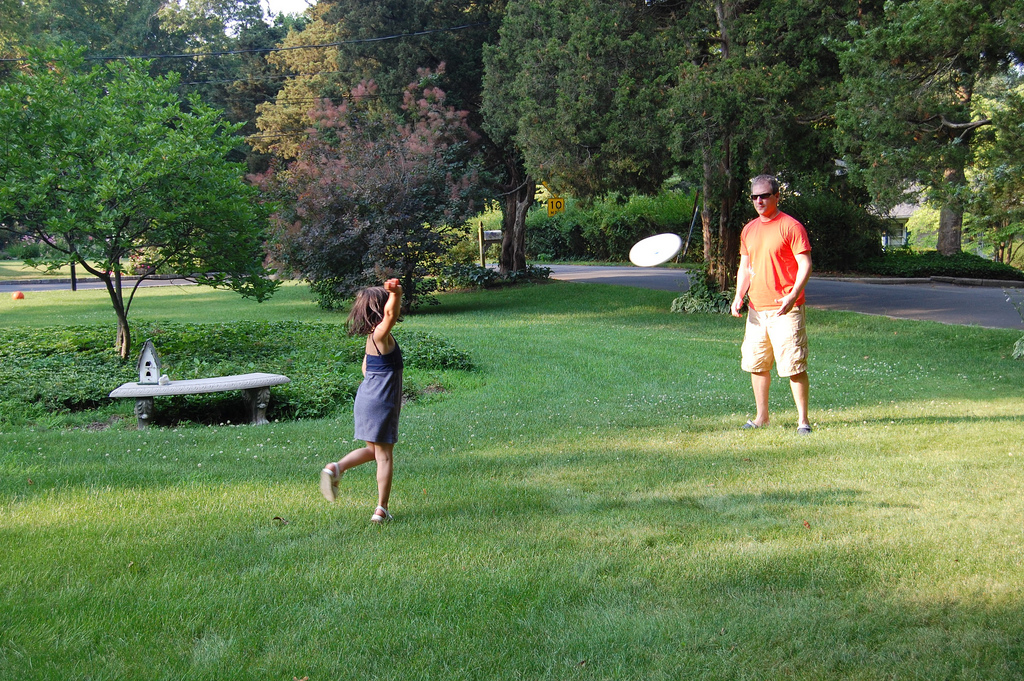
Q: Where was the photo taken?
A: In a park.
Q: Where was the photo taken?
A: In a park.